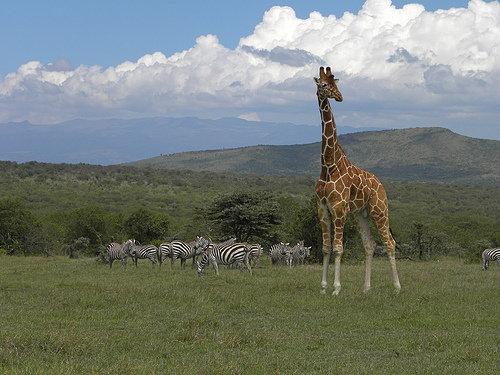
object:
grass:
[176, 327, 386, 366]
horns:
[325, 66, 332, 76]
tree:
[122, 206, 171, 249]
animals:
[62, 62, 498, 299]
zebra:
[290, 241, 307, 265]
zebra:
[103, 239, 137, 270]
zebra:
[157, 240, 182, 268]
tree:
[3, 210, 51, 259]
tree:
[60, 206, 112, 260]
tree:
[203, 189, 284, 247]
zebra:
[123, 239, 161, 271]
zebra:
[168, 235, 208, 270]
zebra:
[196, 243, 254, 279]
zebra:
[268, 241, 293, 268]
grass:
[92, 291, 270, 344]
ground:
[4, 256, 497, 373]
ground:
[319, 190, 354, 231]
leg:
[351, 216, 376, 292]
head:
[311, 65, 344, 104]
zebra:
[193, 236, 239, 271]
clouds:
[350, 0, 499, 79]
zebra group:
[103, 234, 313, 278]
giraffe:
[311, 66, 403, 298]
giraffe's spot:
[375, 183, 387, 202]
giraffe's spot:
[332, 200, 348, 219]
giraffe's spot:
[321, 109, 334, 123]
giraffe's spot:
[326, 136, 338, 150]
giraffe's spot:
[334, 233, 344, 241]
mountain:
[101, 125, 498, 185]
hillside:
[144, 125, 457, 217]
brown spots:
[333, 175, 345, 196]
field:
[1, 249, 498, 373]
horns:
[318, 65, 326, 78]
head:
[126, 238, 135, 252]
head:
[278, 240, 289, 256]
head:
[193, 237, 202, 248]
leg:
[317, 207, 332, 287]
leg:
[326, 204, 348, 289]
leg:
[366, 206, 400, 285]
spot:
[340, 173, 351, 187]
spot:
[324, 182, 335, 194]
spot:
[333, 129, 340, 142]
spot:
[377, 210, 385, 219]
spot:
[327, 204, 332, 210]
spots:
[350, 165, 365, 176]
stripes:
[211, 246, 243, 264]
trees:
[288, 196, 361, 264]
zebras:
[242, 242, 265, 269]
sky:
[0, 0, 462, 118]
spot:
[325, 120, 333, 136]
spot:
[346, 167, 354, 178]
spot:
[316, 177, 326, 198]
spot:
[375, 182, 387, 202]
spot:
[347, 200, 357, 211]